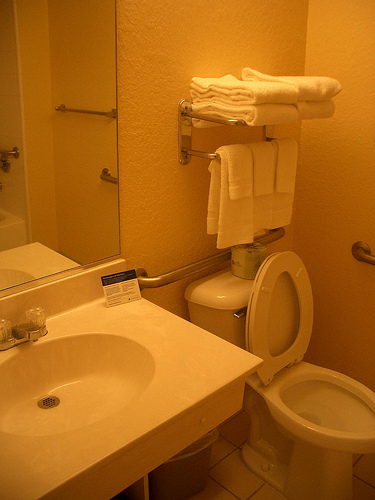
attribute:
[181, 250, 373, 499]
toilet — open, whtie, white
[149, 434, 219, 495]
can — trash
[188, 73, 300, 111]
towel — stacked, white, folded, hanging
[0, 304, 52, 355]
fuacet — white, silver, clear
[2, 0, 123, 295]
mirror — reflective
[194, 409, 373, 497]
floor — tiled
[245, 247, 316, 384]
seat — raised, up